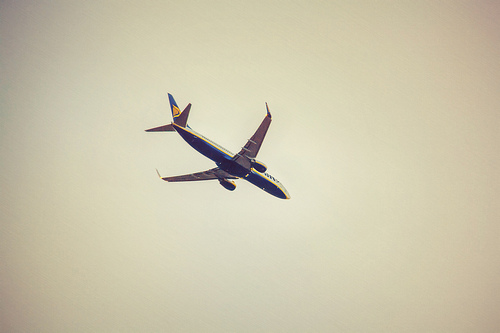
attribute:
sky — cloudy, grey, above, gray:
[0, 0, 498, 332]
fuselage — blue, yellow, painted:
[183, 133, 275, 187]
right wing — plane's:
[231, 98, 273, 174]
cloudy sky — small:
[1, 2, 498, 332]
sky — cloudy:
[428, 188, 468, 223]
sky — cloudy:
[283, 5, 499, 330]